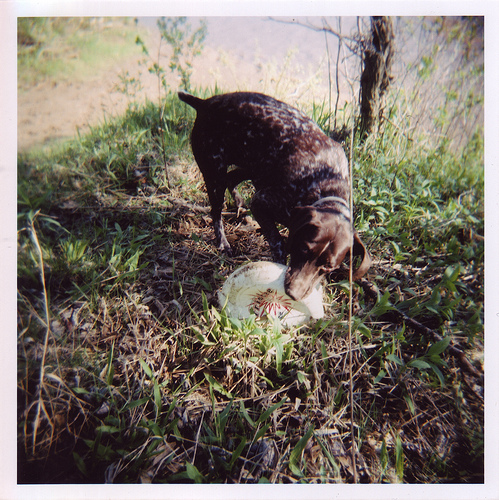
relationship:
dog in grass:
[206, 103, 383, 235] [397, 235, 446, 336]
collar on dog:
[319, 186, 348, 207] [206, 103, 383, 235]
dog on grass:
[206, 103, 383, 235] [397, 235, 446, 336]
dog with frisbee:
[206, 103, 383, 235] [245, 267, 296, 311]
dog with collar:
[206, 103, 383, 235] [319, 186, 348, 207]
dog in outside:
[206, 103, 383, 235] [112, 88, 362, 367]